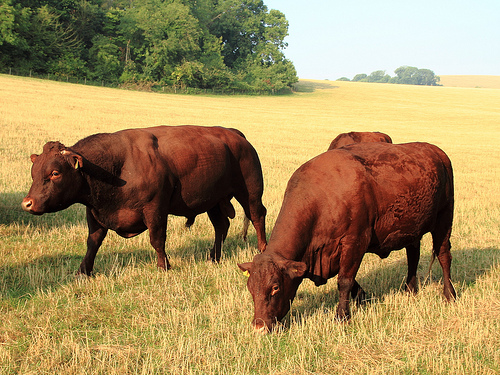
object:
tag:
[74, 158, 78, 170]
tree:
[240, 40, 300, 95]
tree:
[255, 2, 294, 46]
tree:
[140, 19, 230, 89]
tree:
[66, 37, 123, 79]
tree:
[0, 0, 83, 72]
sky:
[259, 0, 498, 85]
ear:
[237, 260, 252, 276]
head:
[15, 143, 88, 215]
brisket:
[304, 244, 341, 276]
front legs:
[329, 252, 376, 323]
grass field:
[0, 66, 498, 373]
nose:
[17, 193, 40, 213]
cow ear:
[67, 153, 82, 170]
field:
[4, 68, 495, 373]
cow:
[23, 96, 262, 296]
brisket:
[95, 203, 145, 241]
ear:
[26, 151, 43, 165]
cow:
[216, 131, 496, 345]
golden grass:
[2, 79, 499, 374]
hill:
[432, 70, 499, 90]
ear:
[269, 253, 321, 288]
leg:
[403, 239, 420, 292]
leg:
[430, 226, 458, 297]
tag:
[241, 267, 250, 277]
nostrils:
[17, 198, 32, 209]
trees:
[1, 1, 302, 101]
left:
[5, 178, 144, 310]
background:
[1, 68, 496, 180]